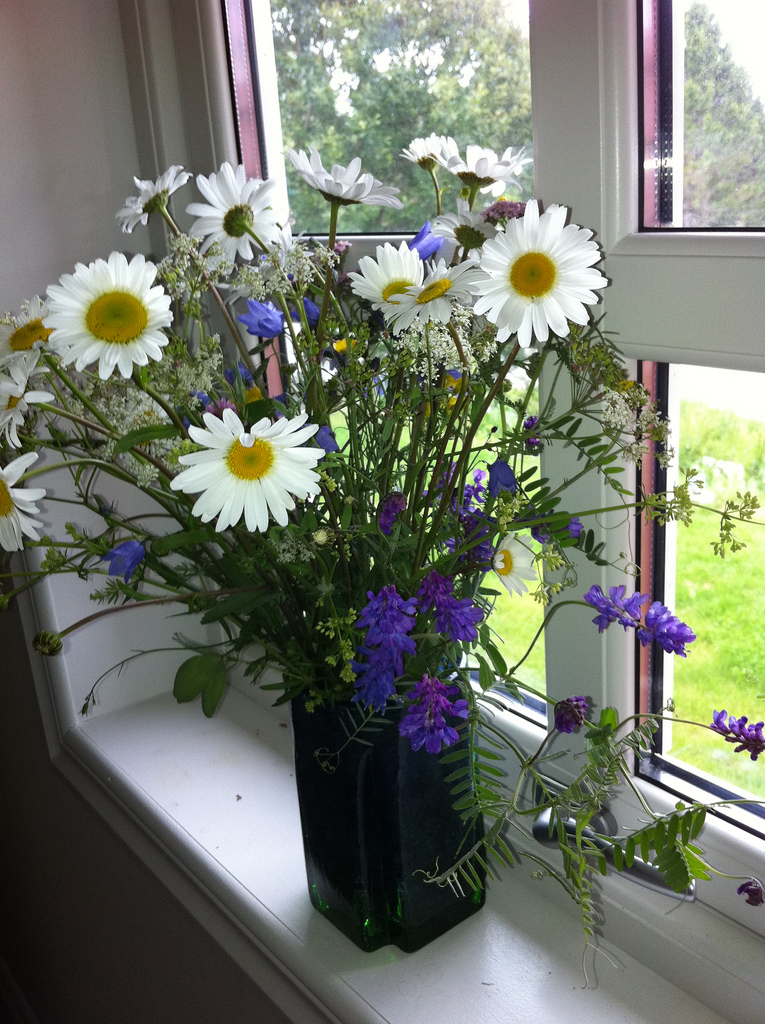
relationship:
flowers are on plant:
[343, 578, 484, 754] [64, 172, 641, 719]